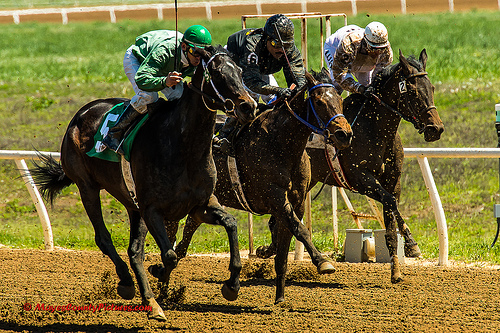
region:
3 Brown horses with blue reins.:
[13, 23, 498, 326]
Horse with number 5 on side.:
[0, 1, 258, 331]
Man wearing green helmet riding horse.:
[10, 16, 256, 319]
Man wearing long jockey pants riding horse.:
[10, 20, 245, 320]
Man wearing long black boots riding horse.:
[6, 20, 256, 321]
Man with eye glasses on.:
[81, 20, 221, 165]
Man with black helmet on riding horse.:
[210, 11, 352, 306]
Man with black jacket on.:
[225, 7, 312, 105]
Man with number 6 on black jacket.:
[225, 10, 310, 110]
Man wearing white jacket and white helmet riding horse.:
[315, 18, 446, 283]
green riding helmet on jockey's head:
[178, 25, 209, 53]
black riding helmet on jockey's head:
[259, 15, 295, 42]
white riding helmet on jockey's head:
[362, 21, 389, 50]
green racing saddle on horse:
[87, 98, 149, 166]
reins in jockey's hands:
[176, 78, 230, 107]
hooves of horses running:
[100, 238, 426, 319]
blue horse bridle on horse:
[282, 82, 347, 138]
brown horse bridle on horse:
[357, 68, 439, 125]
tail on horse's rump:
[16, 144, 75, 204]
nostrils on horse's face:
[332, 128, 353, 140]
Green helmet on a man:
[174, 16, 216, 52]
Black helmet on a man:
[258, 8, 303, 50]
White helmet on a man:
[360, 15, 389, 49]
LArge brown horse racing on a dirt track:
[42, 83, 249, 319]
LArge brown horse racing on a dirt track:
[236, 85, 346, 312]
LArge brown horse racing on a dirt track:
[319, 44, 449, 329]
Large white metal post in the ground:
[5, 8, 30, 30]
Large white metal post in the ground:
[407, 147, 459, 300]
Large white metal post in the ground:
[6, 147, 61, 259]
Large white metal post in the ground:
[144, 4, 176, 19]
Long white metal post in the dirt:
[10, 151, 55, 269]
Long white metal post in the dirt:
[235, 211, 252, 248]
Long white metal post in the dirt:
[324, 191, 342, 252]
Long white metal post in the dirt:
[413, 146, 459, 283]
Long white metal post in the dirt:
[395, 1, 410, 16]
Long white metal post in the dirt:
[10, 7, 22, 21]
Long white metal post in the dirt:
[53, 4, 73, 23]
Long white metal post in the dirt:
[103, 4, 121, 23]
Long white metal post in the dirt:
[146, 5, 181, 27]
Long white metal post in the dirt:
[196, 3, 221, 22]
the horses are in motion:
[97, 0, 478, 300]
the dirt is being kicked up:
[76, 217, 366, 324]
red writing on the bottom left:
[10, 260, 169, 327]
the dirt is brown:
[131, 245, 438, 329]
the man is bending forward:
[108, 12, 231, 78]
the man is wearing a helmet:
[160, 2, 225, 59]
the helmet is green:
[155, 12, 225, 67]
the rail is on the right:
[1, 110, 472, 278]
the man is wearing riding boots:
[65, 65, 178, 178]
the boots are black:
[85, 83, 163, 157]